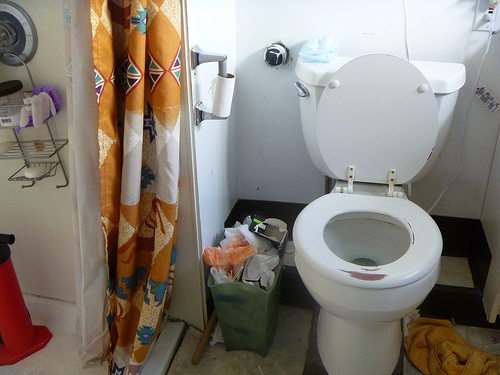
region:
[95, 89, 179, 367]
the shower curtain is multi colored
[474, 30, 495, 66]
the cord is white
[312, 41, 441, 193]
the toilet seat is up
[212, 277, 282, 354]
the can is green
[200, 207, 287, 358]
the can is full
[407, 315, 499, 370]
the yellow cloth is on the floor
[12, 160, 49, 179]
the soap is on the rack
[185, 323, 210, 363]
the handle is wooden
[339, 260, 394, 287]
the paint is coming off of the seat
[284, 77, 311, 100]
the handle is silver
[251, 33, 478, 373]
A white toilet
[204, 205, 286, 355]
A full green trash can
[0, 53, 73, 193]
A shower storage rack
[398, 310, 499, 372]
A towel on the floor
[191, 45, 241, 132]
A toilet paper holder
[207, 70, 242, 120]
A roll of toilet paper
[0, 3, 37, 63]
A shower faucet control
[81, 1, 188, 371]
A patterned shower curtain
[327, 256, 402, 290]
Scuffs on the toilet seat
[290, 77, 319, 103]
The flusher on a toilet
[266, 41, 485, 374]
toilet made of white porcelain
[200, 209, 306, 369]
trash can full of garbage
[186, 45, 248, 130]
roll of toilet paper on holder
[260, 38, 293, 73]
cleanout plug on a wall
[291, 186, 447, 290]
wooden toilet seat with fading paint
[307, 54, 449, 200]
white lid of a toilet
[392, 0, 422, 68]
white cord above a toilet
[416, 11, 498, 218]
white cord on a wall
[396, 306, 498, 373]
orange towel on the floor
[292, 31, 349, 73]
blue fluffy shower sponge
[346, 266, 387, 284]
brown mark on the toilet seat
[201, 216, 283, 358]
small trash can that is overflowing with garbage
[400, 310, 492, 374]
something yellow laying on the ground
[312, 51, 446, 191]
toilet lid is up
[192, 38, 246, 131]
sideways toilet paper holder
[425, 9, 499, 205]
white wire running down the wall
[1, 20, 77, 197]
silver shower caddy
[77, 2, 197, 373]
patterned shower curtain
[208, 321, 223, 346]
trash that has fallen out of the can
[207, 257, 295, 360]
small green trash can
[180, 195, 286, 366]
Trash can is overflowing.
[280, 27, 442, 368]
The toilet is white.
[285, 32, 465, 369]
Toilet led is up.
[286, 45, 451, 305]
Toilet seat is worn.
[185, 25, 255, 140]
Toilet paper on holder.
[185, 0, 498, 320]
Bathroom wall is white.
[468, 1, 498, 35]
Plug outlet behind toilet.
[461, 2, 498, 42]
White plug in outlet.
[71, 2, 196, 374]
Shower curtain is colorful.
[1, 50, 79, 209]
Rack hanging in shower.